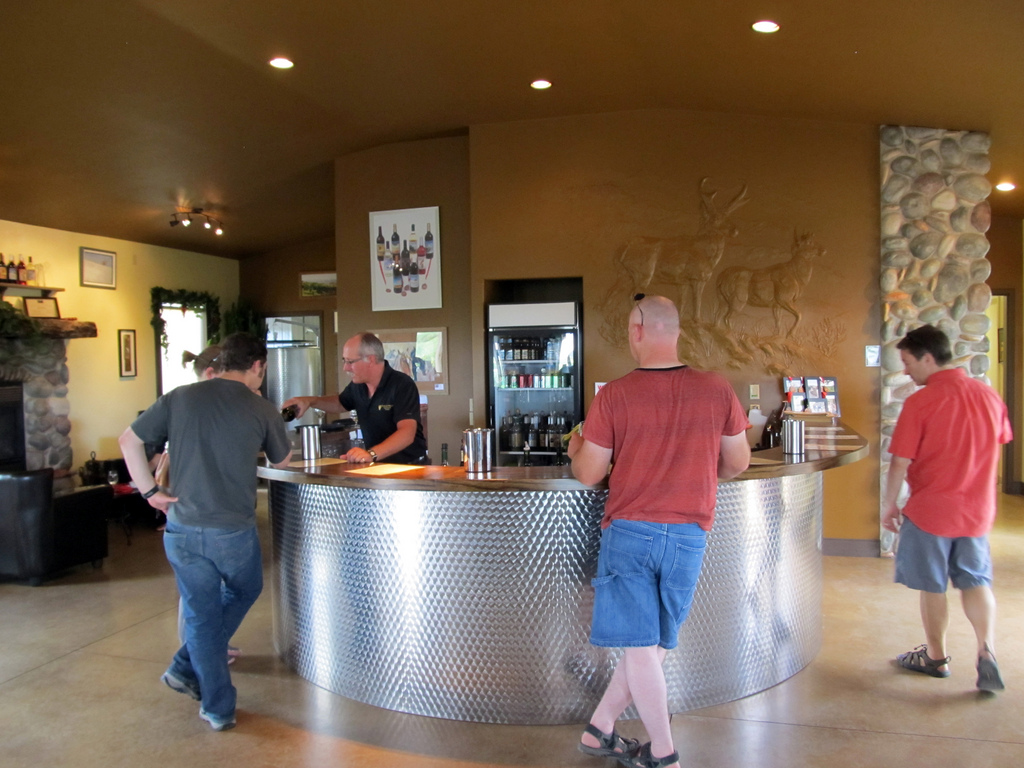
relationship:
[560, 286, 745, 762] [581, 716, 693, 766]
man wearing sandals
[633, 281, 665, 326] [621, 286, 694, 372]
sunglasses are on head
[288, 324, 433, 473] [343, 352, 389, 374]
bartender has glasses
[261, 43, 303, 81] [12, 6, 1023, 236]
lighting on ceiling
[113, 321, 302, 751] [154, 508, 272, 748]
man wearing jeans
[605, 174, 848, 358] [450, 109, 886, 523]
deer on wall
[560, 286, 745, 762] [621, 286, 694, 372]
man has head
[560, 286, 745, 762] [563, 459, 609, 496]
man has elbow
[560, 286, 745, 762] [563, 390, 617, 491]
man has arm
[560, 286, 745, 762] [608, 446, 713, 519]
man has back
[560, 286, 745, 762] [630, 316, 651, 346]
man has ear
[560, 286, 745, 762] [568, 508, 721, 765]
man has legs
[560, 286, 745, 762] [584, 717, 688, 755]
man has feet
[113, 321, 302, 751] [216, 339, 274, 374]
man has hair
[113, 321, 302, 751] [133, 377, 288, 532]
man wearing shirt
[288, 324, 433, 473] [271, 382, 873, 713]
bartender behind bar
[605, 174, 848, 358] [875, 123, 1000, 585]
deer on wall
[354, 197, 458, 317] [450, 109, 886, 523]
artwork on wall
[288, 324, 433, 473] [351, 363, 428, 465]
bartender wearing shirt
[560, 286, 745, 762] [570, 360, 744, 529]
man wearing shirt